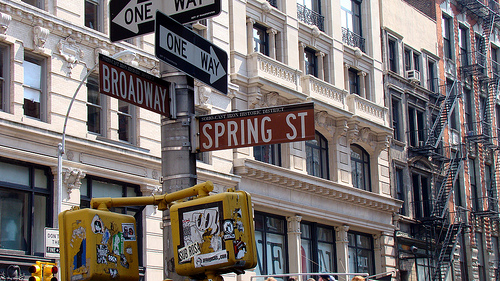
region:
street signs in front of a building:
[62, 2, 312, 279]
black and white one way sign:
[151, 10, 236, 88]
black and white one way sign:
[111, 0, 226, 30]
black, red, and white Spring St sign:
[197, 108, 324, 150]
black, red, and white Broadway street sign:
[94, 55, 187, 118]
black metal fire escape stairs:
[409, 7, 494, 271]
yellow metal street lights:
[48, 183, 262, 275]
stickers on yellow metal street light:
[176, 198, 257, 274]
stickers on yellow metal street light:
[65, 213, 144, 279]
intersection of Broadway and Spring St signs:
[97, 35, 320, 160]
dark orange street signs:
[91, 57, 313, 149]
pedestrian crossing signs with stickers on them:
[162, 190, 259, 272]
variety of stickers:
[65, 199, 257, 274]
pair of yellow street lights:
[28, 257, 62, 279]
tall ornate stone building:
[235, 5, 399, 272]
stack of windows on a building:
[381, 26, 449, 271]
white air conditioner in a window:
[406, 68, 419, 83]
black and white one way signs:
[107, 0, 227, 95]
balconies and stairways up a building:
[413, 2, 498, 278]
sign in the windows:
[250, 223, 363, 279]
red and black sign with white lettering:
[192, 100, 317, 150]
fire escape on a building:
[420, 75, 460, 280]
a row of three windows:
[240, 20, 370, 95]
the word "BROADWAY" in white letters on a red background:
[100, 60, 170, 110]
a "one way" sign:
[151, 10, 231, 90]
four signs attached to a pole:
[95, 0, 315, 180]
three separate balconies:
[250, 50, 395, 131]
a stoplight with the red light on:
[27, 260, 62, 279]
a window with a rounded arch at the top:
[345, 140, 370, 190]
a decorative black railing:
[342, 29, 364, 50]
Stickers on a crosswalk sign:
[176, 194, 258, 272]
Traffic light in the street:
[30, 261, 95, 279]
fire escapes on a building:
[411, 85, 471, 268]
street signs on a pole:
[95, 44, 300, 161]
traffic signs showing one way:
[135, 13, 253, 86]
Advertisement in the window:
[259, 219, 367, 279]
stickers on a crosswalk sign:
[60, 191, 309, 273]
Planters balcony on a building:
[281, 11, 376, 61]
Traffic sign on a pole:
[33, 220, 80, 264]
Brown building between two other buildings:
[249, 3, 398, 252]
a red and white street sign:
[193, 98, 318, 153]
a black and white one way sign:
[152, 5, 240, 94]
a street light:
[51, 40, 141, 224]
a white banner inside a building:
[247, 230, 360, 279]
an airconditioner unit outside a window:
[402, 69, 424, 84]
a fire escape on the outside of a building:
[404, 76, 465, 173]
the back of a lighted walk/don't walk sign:
[167, 178, 258, 277]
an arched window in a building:
[345, 138, 381, 197]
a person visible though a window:
[1, 215, 19, 245]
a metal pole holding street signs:
[155, 20, 199, 278]